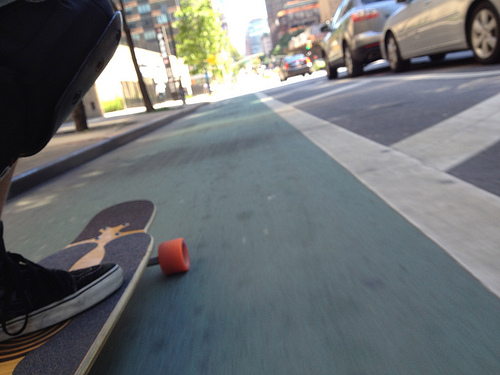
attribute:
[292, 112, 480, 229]
line — white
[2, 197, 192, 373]
skateboard — black, designed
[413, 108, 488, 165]
line — white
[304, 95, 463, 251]
lines — white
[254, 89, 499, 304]
line — white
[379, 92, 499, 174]
line — white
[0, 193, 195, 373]
skateboarder — going down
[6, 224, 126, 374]
shoes — worn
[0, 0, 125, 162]
pads — protective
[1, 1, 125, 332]
person — skateboarding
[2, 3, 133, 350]
person — wearing, skateboarding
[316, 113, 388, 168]
line — white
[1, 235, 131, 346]
shoe — black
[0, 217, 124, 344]
shoe — black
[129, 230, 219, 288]
wheels — orange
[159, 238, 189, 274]
wheel — orange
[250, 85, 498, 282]
line — white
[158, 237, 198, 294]
wheels — red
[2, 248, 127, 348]
shoe — black, white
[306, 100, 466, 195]
line — white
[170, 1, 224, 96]
tree — green